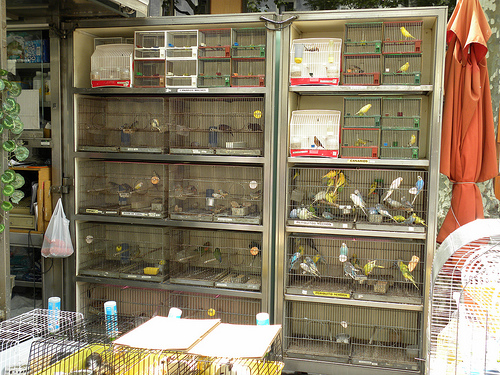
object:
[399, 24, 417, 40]
bird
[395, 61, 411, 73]
bird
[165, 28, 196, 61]
cage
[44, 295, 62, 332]
water bottle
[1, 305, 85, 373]
cage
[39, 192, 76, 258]
bag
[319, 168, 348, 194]
multiple birds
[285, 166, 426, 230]
crate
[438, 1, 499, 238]
umbrella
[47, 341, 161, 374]
yellow bottom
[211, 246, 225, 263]
birds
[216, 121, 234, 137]
birds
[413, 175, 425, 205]
blue bird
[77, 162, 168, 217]
cage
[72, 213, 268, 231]
shelf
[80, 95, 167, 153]
cages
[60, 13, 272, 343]
unit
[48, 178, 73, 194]
hook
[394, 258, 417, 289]
bird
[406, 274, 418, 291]
long tail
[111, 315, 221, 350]
folder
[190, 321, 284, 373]
cages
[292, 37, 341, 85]
cage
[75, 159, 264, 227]
two cages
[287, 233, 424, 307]
crate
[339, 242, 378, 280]
multiple birds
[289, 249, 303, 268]
colorful bird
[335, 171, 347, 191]
yellow bird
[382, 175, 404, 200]
white bird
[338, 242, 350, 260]
blue bird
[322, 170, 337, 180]
yellow bird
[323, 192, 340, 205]
yellow bird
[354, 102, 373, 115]
parakeet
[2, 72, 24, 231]
vine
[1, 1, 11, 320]
pole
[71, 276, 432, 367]
bottom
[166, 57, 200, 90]
cage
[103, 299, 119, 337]
water bottle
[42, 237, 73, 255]
red bag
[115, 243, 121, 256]
bird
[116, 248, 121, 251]
yellow breast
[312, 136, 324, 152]
brown bird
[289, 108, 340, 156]
white cage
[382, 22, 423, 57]
crate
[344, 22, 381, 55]
green cage